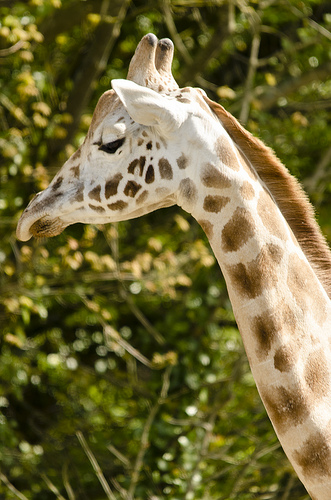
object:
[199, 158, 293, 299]
brown spots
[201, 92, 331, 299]
brown mane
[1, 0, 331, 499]
trees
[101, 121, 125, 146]
white eyelid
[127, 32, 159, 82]
short horns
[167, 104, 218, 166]
white spot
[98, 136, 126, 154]
giraffe eye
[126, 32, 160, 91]
giraffe horn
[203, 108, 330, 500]
giraffe neck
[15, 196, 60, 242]
giraffe mouth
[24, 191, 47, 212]
giraffe nose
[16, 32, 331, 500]
giraffe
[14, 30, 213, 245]
head/neck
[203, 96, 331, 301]
short hair/mane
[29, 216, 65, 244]
bottom lip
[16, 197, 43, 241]
top lip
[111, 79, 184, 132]
ear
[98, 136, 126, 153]
eyelashes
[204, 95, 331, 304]
hair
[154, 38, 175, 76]
horns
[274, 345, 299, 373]
spot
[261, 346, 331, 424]
spot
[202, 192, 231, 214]
spot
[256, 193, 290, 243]
spot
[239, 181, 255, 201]
spot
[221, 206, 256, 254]
spot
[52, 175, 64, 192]
spot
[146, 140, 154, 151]
spot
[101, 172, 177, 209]
dots